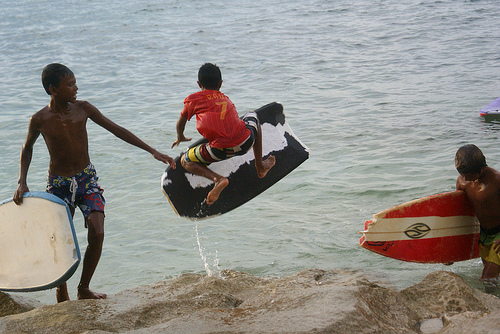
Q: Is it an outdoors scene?
A: Yes, it is outdoors.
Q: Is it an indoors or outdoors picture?
A: It is outdoors.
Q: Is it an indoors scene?
A: No, it is outdoors.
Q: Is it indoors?
A: No, it is outdoors.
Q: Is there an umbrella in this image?
A: No, there are no umbrellas.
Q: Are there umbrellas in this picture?
A: No, there are no umbrellas.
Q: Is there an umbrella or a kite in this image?
A: No, there are no umbrellas or kites.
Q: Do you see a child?
A: Yes, there are children.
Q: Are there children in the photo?
A: Yes, there are children.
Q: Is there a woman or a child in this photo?
A: Yes, there are children.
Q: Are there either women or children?
A: Yes, there are children.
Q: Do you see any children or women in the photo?
A: Yes, there are children.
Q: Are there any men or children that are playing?
A: Yes, the children are playing.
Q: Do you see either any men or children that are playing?
A: Yes, the children are playing.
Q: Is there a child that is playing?
A: Yes, there are children that are playing.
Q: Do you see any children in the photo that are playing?
A: Yes, there are children that are playing.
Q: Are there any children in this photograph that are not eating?
A: Yes, there are children that are playing.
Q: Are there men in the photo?
A: No, there are no men.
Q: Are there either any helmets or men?
A: No, there are no men or helmets.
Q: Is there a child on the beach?
A: Yes, there are children on the beach.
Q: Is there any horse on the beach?
A: No, there are children on the beach.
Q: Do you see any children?
A: Yes, there are children.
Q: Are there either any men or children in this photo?
A: Yes, there are children.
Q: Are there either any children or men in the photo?
A: Yes, there are children.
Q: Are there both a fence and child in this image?
A: No, there are children but no fences.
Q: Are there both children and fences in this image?
A: No, there are children but no fences.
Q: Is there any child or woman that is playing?
A: Yes, the children are playing.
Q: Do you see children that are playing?
A: Yes, there are children that are playing.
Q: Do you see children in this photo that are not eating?
A: Yes, there are children that are playing .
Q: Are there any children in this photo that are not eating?
A: Yes, there are children that are playing.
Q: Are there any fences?
A: No, there are no fences.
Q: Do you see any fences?
A: No, there are no fences.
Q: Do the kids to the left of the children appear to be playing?
A: Yes, the kids are playing.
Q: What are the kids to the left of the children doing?
A: The kids are playing.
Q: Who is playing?
A: The kids are playing.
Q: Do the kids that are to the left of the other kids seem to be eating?
A: No, the kids are playing.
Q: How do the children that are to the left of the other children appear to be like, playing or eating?
A: The kids are playing.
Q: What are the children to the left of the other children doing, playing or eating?
A: The children are playing.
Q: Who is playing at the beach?
A: The children are playing at the beach.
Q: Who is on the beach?
A: The children are on the beach.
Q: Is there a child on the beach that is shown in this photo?
A: Yes, there are children on the beach.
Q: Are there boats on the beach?
A: No, there are children on the beach.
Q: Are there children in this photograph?
A: Yes, there are children.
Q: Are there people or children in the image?
A: Yes, there are children.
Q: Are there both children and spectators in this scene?
A: No, there are children but no spectators.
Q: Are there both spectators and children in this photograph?
A: No, there are children but no spectators.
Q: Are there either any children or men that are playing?
A: Yes, the children are playing.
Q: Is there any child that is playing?
A: Yes, there are children that are playing.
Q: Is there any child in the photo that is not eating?
A: Yes, there are children that are playing.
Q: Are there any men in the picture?
A: No, there are no men.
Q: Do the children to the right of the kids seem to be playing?
A: Yes, the kids are playing.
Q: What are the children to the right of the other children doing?
A: The children are playing.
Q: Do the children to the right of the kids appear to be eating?
A: No, the kids are playing.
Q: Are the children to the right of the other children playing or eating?
A: The kids are playing.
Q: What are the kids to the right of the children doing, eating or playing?
A: The children are playing.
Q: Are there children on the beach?
A: Yes, there are children on the beach.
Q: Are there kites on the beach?
A: No, there are children on the beach.